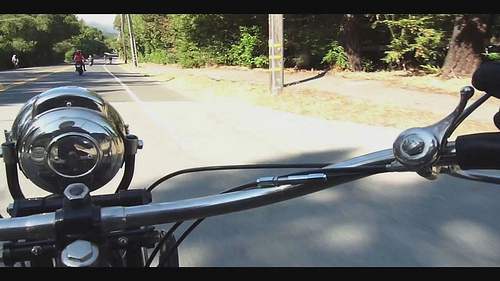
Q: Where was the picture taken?
A: It was taken at the road.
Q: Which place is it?
A: It is a road.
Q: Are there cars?
A: No, there are no cars.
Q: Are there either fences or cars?
A: No, there are no cars or fences.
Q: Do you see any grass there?
A: Yes, there is grass.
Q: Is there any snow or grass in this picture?
A: Yes, there is grass.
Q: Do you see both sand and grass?
A: No, there is grass but no sand.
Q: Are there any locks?
A: No, there are no locks.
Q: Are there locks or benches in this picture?
A: No, there are no locks or benches.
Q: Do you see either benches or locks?
A: No, there are no locks or benches.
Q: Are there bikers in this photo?
A: Yes, there is a biker.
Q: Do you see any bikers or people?
A: Yes, there is a biker.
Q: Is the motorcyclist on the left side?
A: Yes, the motorcyclist is on the left of the image.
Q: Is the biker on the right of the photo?
A: No, the biker is on the left of the image.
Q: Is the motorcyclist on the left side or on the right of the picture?
A: The motorcyclist is on the left of the image.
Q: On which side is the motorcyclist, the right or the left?
A: The motorcyclist is on the left of the image.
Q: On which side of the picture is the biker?
A: The biker is on the left of the image.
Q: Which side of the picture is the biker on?
A: The biker is on the left of the image.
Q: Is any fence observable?
A: No, there are no fences.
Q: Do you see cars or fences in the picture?
A: No, there are no fences or cars.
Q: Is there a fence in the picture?
A: No, there are no fences.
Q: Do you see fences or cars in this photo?
A: No, there are no fences or cars.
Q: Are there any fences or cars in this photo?
A: No, there are no fences or cars.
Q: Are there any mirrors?
A: Yes, there is a mirror.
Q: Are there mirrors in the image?
A: Yes, there is a mirror.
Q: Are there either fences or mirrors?
A: Yes, there is a mirror.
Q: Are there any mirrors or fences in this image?
A: Yes, there is a mirror.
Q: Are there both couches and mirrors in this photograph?
A: No, there is a mirror but no couches.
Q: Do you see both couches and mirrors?
A: No, there is a mirror but no couches.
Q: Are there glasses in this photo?
A: No, there are no glasses.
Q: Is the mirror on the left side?
A: Yes, the mirror is on the left of the image.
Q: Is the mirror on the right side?
A: No, the mirror is on the left of the image.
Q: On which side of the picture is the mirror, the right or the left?
A: The mirror is on the left of the image.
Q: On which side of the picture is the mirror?
A: The mirror is on the left of the image.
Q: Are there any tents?
A: No, there are no tents.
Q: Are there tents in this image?
A: No, there are no tents.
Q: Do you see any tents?
A: No, there are no tents.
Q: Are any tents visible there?
A: No, there are no tents.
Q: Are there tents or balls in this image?
A: No, there are no tents or balls.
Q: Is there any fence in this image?
A: No, there are no fences.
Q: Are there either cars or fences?
A: No, there are no fences or cars.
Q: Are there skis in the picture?
A: No, there are no skis.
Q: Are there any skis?
A: No, there are no skis.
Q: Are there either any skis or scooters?
A: No, there are no skis or scooters.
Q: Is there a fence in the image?
A: No, there are no fences.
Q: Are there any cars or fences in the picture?
A: No, there are no fences or cars.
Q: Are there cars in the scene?
A: No, there are no cars.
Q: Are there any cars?
A: No, there are no cars.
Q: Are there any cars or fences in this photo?
A: No, there are no cars or fences.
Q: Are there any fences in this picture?
A: No, there are no fences.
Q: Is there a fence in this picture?
A: No, there are no fences.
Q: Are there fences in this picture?
A: No, there are no fences.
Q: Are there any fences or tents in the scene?
A: No, there are no fences or tents.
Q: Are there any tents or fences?
A: No, there are no fences or tents.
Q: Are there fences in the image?
A: No, there are no fences.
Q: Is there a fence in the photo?
A: No, there are no fences.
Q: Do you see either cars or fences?
A: No, there are no fences or cars.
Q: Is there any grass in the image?
A: Yes, there is grass.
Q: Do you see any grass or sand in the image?
A: Yes, there is grass.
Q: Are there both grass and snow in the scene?
A: No, there is grass but no snow.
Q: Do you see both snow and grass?
A: No, there is grass but no snow.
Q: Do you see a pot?
A: No, there are no pots.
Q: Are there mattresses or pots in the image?
A: No, there are no pots or mattresses.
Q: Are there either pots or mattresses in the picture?
A: No, there are no pots or mattresses.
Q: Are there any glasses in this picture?
A: No, there are no glasses.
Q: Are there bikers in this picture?
A: Yes, there is a biker.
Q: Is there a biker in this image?
A: Yes, there is a biker.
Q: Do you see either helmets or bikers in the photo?
A: Yes, there is a biker.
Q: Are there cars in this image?
A: No, there are no cars.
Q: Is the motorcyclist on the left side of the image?
A: Yes, the motorcyclist is on the left of the image.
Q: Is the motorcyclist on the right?
A: No, the motorcyclist is on the left of the image.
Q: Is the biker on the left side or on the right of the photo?
A: The biker is on the left of the image.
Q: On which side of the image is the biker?
A: The biker is on the left of the image.